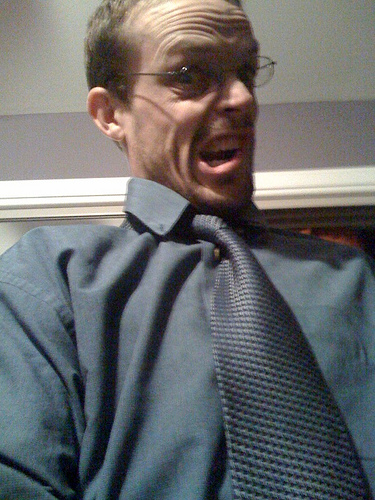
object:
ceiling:
[0, 0, 374, 114]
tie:
[189, 211, 374, 499]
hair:
[82, 0, 244, 156]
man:
[0, 2, 375, 498]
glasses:
[97, 55, 275, 88]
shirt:
[0, 175, 374, 500]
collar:
[120, 175, 267, 239]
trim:
[0, 162, 375, 226]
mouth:
[196, 121, 254, 177]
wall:
[0, 0, 375, 225]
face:
[128, 0, 260, 219]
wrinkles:
[145, 0, 255, 62]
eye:
[171, 62, 207, 86]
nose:
[213, 67, 253, 114]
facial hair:
[192, 111, 255, 146]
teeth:
[198, 134, 242, 166]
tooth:
[213, 138, 220, 155]